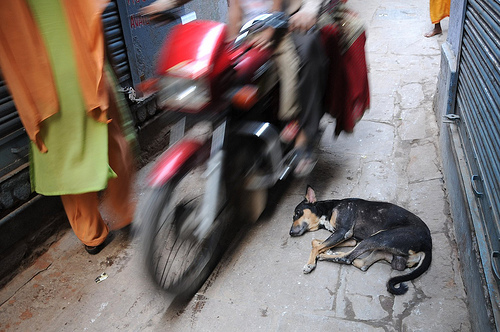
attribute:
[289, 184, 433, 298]
dog — laying, black, resting,  dead, brown, tan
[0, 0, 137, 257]
outfit — yellow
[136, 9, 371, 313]
motorcycle — red, driving, moving, in motion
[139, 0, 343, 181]
people — driving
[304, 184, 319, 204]
ear — up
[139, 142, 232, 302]
wheel — black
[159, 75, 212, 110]
light — white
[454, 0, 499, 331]
door — metal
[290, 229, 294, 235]
nose — black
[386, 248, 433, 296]
tail — curled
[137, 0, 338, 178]
man — riding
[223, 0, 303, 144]
child — riding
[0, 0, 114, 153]
scarf — orange